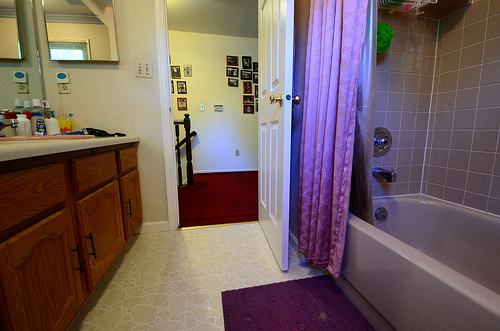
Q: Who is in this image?
A: No one.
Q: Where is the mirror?
A: On the wall.